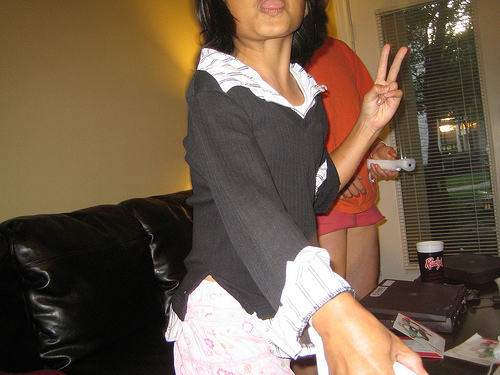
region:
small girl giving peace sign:
[170, 8, 437, 374]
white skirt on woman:
[144, 281, 269, 373]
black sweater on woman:
[173, 84, 334, 278]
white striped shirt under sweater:
[195, 34, 306, 115]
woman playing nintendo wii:
[305, 16, 425, 295]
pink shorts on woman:
[327, 196, 390, 235]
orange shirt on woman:
[310, 38, 372, 238]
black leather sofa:
[13, 197, 173, 363]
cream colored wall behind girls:
[5, 15, 221, 192]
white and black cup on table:
[405, 220, 458, 281]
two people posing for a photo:
[224, 59, 434, 371]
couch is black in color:
[33, 229, 112, 338]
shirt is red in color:
[319, 47, 377, 131]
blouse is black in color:
[230, 130, 310, 226]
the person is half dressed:
[323, 217, 403, 301]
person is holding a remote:
[333, 108, 461, 206]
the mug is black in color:
[401, 220, 440, 285]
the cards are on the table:
[367, 304, 498, 366]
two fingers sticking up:
[351, 44, 419, 158]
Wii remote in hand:
[358, 142, 453, 193]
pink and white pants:
[151, 292, 314, 372]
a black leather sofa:
[16, 182, 281, 373]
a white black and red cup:
[406, 234, 461, 307]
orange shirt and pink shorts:
[304, 37, 399, 257]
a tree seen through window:
[414, 8, 499, 261]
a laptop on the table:
[359, 259, 477, 348]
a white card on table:
[381, 304, 481, 373]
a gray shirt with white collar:
[146, 29, 368, 351]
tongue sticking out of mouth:
[257, 0, 298, 26]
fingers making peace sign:
[349, 47, 423, 157]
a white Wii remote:
[355, 150, 427, 190]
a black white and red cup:
[410, 234, 458, 289]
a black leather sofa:
[7, 192, 229, 372]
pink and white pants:
[175, 294, 305, 374]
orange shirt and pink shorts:
[293, 39, 390, 251]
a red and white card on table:
[393, 314, 452, 370]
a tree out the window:
[417, 5, 499, 218]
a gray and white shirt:
[148, 47, 354, 344]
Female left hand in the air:
[359, 40, 411, 130]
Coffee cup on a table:
[413, 239, 448, 286]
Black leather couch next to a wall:
[6, 199, 164, 346]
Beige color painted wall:
[13, 78, 162, 187]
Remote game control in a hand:
[363, 151, 417, 182]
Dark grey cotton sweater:
[177, 70, 340, 320]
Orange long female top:
[301, 33, 381, 214]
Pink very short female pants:
[313, 194, 388, 247]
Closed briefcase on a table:
[358, 275, 472, 335]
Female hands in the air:
[330, 140, 401, 202]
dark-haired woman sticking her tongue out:
[166, 1, 429, 373]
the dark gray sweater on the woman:
[171, 65, 341, 326]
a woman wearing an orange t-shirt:
[305, 35, 403, 299]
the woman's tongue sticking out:
[259, 0, 285, 10]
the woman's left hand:
[356, 41, 408, 127]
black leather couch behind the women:
[1, 187, 198, 373]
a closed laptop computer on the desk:
[358, 277, 468, 335]